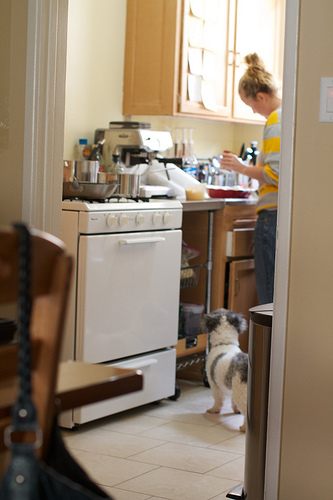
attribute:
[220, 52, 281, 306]
woman — blonde, standing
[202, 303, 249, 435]
dog — waiting, white, short haired, gray, small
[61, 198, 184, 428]
stove — white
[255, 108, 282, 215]
top — yellow, gray, striped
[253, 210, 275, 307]
pants — blue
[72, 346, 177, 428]
drawer — white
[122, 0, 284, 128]
cabinets — wood, brown, wooden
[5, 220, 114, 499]
purse — black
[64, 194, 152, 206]
burners — black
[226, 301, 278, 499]
trash can — black, gray, metal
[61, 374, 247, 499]
floor — white, tiled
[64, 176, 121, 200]
frying pan — silver